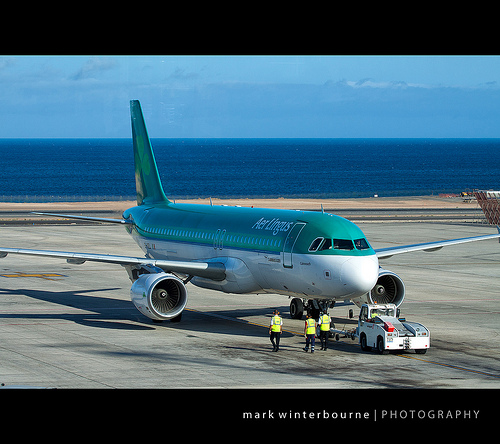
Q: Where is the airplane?
A: On the runway.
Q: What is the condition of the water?
A: Calm.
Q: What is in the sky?
A: Clouds.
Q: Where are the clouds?
A: In the sky.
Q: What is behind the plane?
A: Water.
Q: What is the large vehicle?
A: Plane.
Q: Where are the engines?
A: Under the wings.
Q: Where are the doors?
A: Near the front of the plane.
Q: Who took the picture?
A: Mark Winterbourne.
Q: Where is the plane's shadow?
A: On the runway.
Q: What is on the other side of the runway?
A: Ocean.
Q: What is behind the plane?
A: The ocean.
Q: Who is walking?
A: Employees.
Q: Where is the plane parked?
A: On cement.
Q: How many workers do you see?
A: Three.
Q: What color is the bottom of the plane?
A: White.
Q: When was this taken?
A: In the daytime.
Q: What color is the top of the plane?
A: Green.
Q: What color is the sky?
A: Blue.